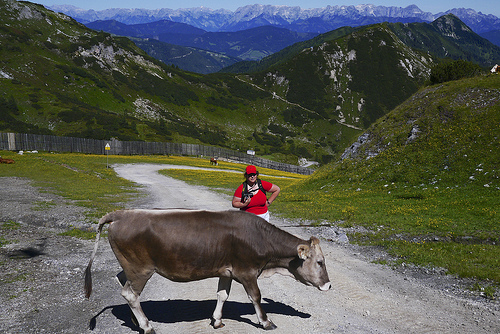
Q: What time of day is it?
A: Daytime.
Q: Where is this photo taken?
A: Outside in the mountains.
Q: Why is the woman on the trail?
A: She is walking.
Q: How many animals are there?
A: One.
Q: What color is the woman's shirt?
A: Red.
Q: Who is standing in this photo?
A: A woman.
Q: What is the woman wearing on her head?
A: A cap.